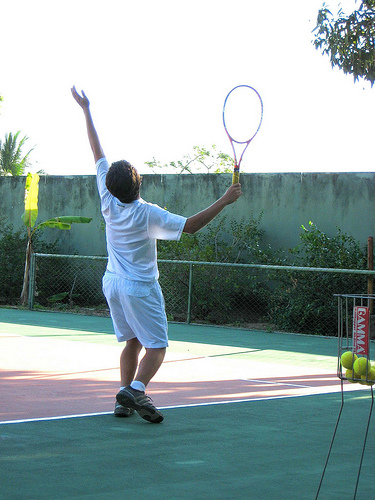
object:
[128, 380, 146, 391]
sock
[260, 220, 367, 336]
bush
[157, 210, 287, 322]
bush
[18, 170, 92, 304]
plant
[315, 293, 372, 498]
basket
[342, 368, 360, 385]
tennis ball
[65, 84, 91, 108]
hand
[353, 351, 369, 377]
tennis balls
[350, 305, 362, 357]
sign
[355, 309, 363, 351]
letters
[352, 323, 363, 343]
m's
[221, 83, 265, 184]
tennis racket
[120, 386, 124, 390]
sock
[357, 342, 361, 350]
white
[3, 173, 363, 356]
wall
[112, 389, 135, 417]
sneakers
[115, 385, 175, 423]
feet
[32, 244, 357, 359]
fence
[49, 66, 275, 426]
man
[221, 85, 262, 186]
racket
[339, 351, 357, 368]
balls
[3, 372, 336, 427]
line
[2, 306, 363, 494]
court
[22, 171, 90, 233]
leaves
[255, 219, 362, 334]
shrub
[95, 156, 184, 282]
shirt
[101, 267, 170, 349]
shorts